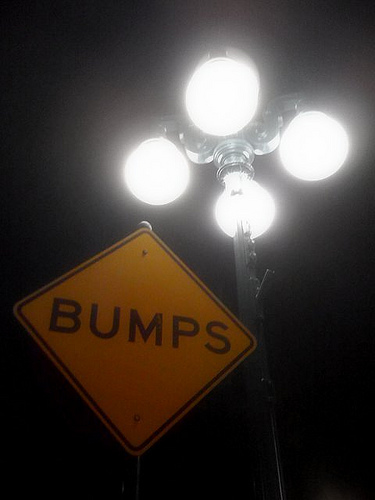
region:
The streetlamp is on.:
[114, 35, 361, 497]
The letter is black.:
[44, 290, 87, 338]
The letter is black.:
[83, 289, 123, 340]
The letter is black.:
[123, 300, 172, 349]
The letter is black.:
[165, 308, 201, 354]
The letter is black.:
[201, 313, 235, 358]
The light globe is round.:
[120, 121, 197, 212]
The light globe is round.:
[212, 167, 283, 248]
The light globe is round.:
[270, 106, 355, 194]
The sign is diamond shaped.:
[16, 214, 258, 462]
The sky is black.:
[301, 275, 365, 323]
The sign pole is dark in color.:
[121, 450, 148, 492]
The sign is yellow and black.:
[12, 223, 260, 457]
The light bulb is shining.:
[215, 175, 277, 241]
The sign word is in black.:
[46, 288, 234, 364]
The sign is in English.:
[50, 291, 231, 357]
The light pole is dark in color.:
[227, 232, 310, 494]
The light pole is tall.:
[225, 232, 279, 445]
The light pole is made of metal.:
[224, 223, 301, 497]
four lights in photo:
[110, 63, 356, 232]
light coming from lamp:
[187, 18, 288, 54]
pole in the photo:
[215, 173, 294, 304]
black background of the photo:
[177, 416, 251, 473]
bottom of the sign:
[100, 404, 176, 466]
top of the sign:
[114, 203, 179, 262]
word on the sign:
[47, 283, 244, 363]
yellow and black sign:
[46, 293, 241, 373]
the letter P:
[159, 303, 210, 358]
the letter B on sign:
[37, 280, 98, 342]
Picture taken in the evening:
[14, 8, 362, 475]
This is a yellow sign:
[15, 209, 260, 463]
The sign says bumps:
[28, 263, 261, 365]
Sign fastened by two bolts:
[131, 247, 162, 432]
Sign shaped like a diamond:
[10, 224, 263, 464]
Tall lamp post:
[209, 61, 287, 479]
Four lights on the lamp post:
[113, 66, 356, 235]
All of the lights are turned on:
[101, 46, 364, 244]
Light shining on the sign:
[80, 206, 254, 307]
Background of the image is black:
[26, 459, 239, 498]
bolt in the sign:
[120, 404, 154, 427]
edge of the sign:
[116, 335, 259, 468]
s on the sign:
[199, 312, 235, 368]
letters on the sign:
[39, 294, 237, 365]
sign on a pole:
[20, 220, 249, 499]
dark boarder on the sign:
[118, 330, 255, 463]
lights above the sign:
[113, 37, 363, 246]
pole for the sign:
[131, 443, 150, 496]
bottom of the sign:
[52, 388, 209, 462]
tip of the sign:
[93, 433, 168, 468]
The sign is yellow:
[17, 224, 257, 453]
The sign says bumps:
[12, 220, 256, 457]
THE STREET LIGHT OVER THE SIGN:
[125, 53, 356, 499]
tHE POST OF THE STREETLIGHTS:
[144, 83, 314, 499]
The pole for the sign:
[124, 451, 143, 494]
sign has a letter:
[51, 296, 81, 333]